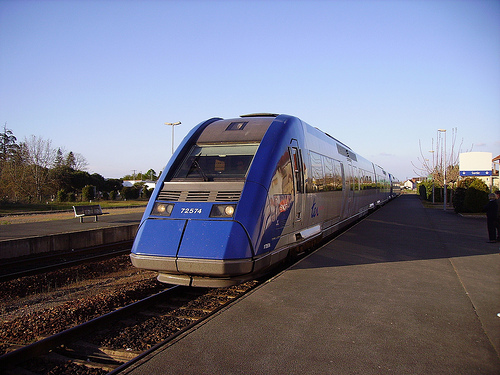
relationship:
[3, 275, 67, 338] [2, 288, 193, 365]
gravel around tracks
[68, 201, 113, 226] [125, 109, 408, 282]
bench besides train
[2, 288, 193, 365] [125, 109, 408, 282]
tracks are for train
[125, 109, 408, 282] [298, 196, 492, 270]
train casts shadow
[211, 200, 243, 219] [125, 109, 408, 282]
left headlight of train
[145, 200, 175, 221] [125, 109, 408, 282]
right headlight of train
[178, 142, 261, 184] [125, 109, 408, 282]
windshield of train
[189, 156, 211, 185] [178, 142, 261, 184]
windshield wiper on windshield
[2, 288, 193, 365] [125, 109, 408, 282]
tracks are in front of train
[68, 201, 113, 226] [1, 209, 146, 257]
bench on platform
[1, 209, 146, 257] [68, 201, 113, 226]
platform has bench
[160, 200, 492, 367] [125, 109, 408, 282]
pavement to right of train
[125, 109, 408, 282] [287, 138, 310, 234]
train has door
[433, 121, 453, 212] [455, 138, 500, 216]
light post at train stop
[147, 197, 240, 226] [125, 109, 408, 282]
two headlights are on train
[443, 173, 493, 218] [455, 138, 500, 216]
hedge at train stop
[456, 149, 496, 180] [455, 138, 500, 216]
sign post at train stop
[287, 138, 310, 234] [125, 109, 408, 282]
door on train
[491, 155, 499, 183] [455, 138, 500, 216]
building behind train stop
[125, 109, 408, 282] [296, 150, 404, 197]
train carries passengers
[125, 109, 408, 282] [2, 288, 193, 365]
train on tracks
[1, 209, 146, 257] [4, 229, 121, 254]
platform made of concrete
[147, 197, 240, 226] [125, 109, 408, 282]
two headlights are on front of train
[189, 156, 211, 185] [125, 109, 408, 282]
windshield wiper on train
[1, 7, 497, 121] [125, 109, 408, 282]
sky above train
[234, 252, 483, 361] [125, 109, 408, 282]
floor beside train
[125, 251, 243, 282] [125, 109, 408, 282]
edge of train